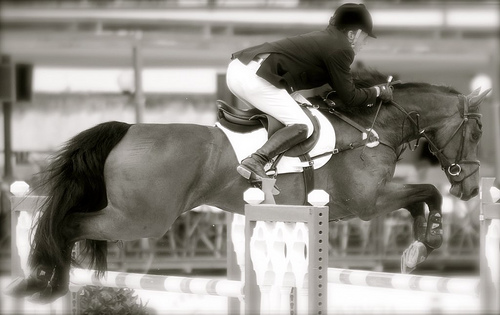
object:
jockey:
[225, 2, 393, 197]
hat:
[329, 2, 380, 40]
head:
[327, 2, 371, 53]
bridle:
[422, 91, 485, 199]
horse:
[5, 82, 493, 295]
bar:
[69, 264, 251, 299]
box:
[241, 202, 328, 314]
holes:
[317, 210, 325, 217]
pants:
[223, 50, 318, 141]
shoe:
[235, 159, 284, 198]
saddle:
[211, 98, 322, 158]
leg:
[367, 181, 448, 245]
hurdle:
[5, 179, 331, 315]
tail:
[12, 119, 130, 305]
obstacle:
[3, 180, 500, 314]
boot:
[236, 122, 311, 197]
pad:
[215, 87, 338, 179]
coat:
[228, 25, 380, 109]